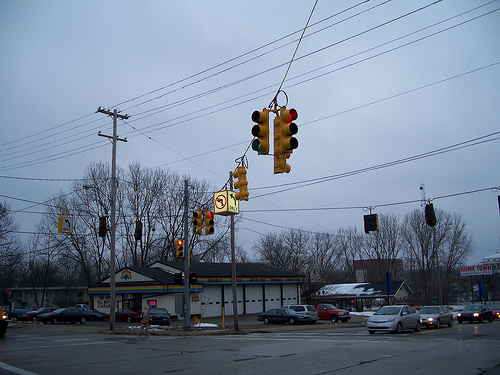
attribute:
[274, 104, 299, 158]
traffic light — yellow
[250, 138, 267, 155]
light — green, on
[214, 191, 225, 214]
sign — white, hanging, bright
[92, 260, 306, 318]
building — white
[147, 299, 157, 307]
sign — red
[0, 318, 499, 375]
road — wet, gray, intersection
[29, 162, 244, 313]
trees — bare, big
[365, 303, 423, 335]
car — silver, stopped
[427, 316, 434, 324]
headlight — on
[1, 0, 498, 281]
sky — dark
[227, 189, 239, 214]
sign — hanging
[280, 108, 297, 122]
light — red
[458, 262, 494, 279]
sign — lettered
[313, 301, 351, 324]
truck — parked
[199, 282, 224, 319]
garage door — closed